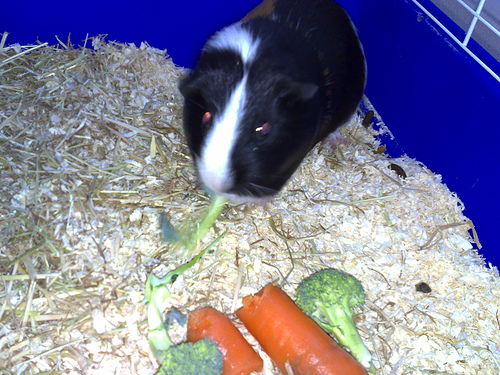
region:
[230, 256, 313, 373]
carrot with bite marks taken out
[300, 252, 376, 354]
floret of green brocolli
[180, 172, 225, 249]
greens being eaten by a guinea pig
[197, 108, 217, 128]
red relfection in an eye of a guinea pig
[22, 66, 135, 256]
straw bedding in an enclosure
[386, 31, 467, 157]
blue wall of an enclosure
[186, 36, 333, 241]
black and white guinea pig eating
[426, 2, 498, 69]
white wire cage wall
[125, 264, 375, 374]
a guinea pig's dinner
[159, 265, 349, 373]
green and orange veggies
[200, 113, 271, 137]
the animal has red eyes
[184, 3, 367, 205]
the animal is black and white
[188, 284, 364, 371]
the carrot is orange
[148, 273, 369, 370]
the broccoli is green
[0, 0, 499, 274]
the container is blue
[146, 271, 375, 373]
vegetable left in cage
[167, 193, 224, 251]
the animal is eating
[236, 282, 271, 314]
the carrot was bit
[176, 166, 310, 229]
the animal has whiskers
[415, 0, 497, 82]
the cage has white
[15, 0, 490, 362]
A black and white gerbil in its cage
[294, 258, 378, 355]
A green piece of broccoli by the carrot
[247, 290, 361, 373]
A large orange carrot by the broccoli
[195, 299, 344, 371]
Two pieces of large orange carrot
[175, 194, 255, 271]
A green vegetable in the gerbil's mouth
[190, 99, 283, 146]
The hamster has small red eyes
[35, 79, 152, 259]
Wood chips lining the hamster's cage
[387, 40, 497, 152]
Plain blue wall on the cage of the hamster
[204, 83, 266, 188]
A white stripe on the hamster's head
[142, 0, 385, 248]
A hamster eating a small piece of broccoli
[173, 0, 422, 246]
Guinea pig in a cage.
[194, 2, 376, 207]
The guinea pig is mostly black.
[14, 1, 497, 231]
Inside of the cage is blue.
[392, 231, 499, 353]
Wood chips on the bottom.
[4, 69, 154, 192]
Hay in the cage.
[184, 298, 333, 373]
Carrots in the cage.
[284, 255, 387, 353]
Broccoli in the cage.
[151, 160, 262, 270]
The guinea pig is eating.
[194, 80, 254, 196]
White on the face.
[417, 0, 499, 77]
Top of the cage is white.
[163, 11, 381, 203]
the guinea pig is black and white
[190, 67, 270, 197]
face of guinea pig is white and black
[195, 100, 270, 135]
eyes of guinea pig are red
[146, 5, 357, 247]
the guinea pig is eating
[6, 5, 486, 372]
the guinea pig is in a cage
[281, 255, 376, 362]
green broccoli in a cage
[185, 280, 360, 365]
two carrots in a cage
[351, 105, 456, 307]
poop of guinea pig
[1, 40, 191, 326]
hay in the cage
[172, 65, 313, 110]
ears of guinea pig are black